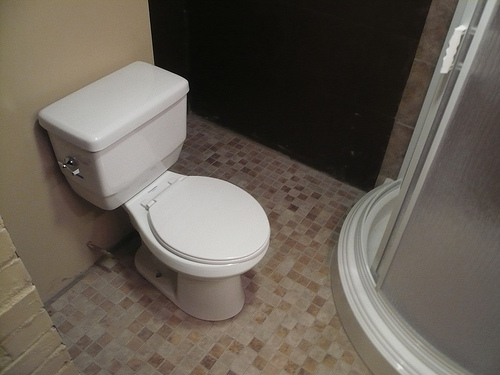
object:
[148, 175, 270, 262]
lid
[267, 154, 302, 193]
floor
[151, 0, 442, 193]
opening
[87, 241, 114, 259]
brown pipes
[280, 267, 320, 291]
floor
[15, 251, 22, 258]
opening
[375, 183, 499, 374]
shower base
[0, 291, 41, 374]
wall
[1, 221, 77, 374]
brick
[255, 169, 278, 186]
tiles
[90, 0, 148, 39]
wall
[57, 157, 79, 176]
handle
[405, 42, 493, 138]
shower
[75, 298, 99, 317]
tile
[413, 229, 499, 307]
shower floor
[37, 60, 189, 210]
water tank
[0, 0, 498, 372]
toilet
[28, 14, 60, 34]
wall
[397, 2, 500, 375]
shower door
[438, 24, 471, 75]
towel